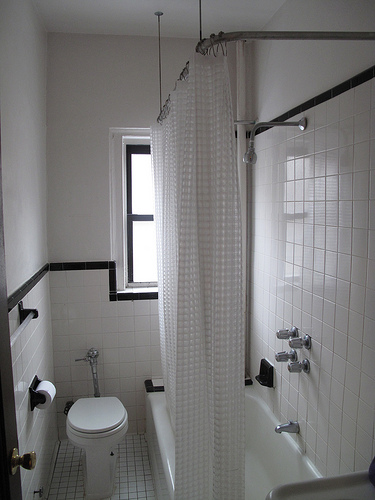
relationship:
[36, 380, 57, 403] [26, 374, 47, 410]
paper on rack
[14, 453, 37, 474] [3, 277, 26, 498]
knob on door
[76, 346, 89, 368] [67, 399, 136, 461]
flusher on toilet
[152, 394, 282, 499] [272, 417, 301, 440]
bathtub has nozzle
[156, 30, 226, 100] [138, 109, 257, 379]
rod on curtain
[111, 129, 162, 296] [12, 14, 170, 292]
window on wall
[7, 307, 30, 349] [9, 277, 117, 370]
towel bar on wall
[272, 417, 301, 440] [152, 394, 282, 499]
faucet in bathtub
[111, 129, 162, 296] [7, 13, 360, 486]
window in bathroom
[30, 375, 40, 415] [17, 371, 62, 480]
paper roll holder on wall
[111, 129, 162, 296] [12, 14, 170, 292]
white trim window on wall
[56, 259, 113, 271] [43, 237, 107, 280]
tile black on wall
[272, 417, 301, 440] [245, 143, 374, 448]
faucet on wall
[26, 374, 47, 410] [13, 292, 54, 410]
rack on wall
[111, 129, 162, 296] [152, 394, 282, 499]
window above bathtub